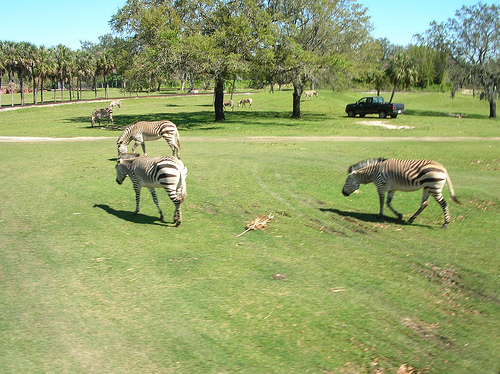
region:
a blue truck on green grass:
[336, 82, 413, 119]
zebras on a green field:
[86, 83, 471, 243]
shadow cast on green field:
[313, 191, 423, 238]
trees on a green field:
[6, 4, 484, 119]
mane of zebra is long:
[346, 153, 391, 178]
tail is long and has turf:
[446, 170, 463, 207]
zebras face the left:
[98, 111, 467, 241]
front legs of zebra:
[373, 193, 409, 225]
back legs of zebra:
[407, 193, 452, 230]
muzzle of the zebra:
[336, 184, 351, 201]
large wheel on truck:
[374, 111, 390, 122]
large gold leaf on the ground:
[223, 205, 284, 249]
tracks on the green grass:
[271, 175, 394, 276]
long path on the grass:
[225, 127, 443, 147]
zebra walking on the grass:
[96, 149, 209, 227]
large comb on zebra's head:
[336, 148, 406, 179]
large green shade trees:
[187, 26, 330, 123]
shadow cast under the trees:
[100, 85, 222, 130]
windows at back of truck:
[367, 92, 389, 104]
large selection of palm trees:
[20, 53, 127, 102]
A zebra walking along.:
[327, 149, 466, 233]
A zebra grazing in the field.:
[105, 118, 186, 159]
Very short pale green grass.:
[67, 260, 187, 330]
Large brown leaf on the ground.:
[220, 206, 282, 251]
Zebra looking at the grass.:
[107, 144, 196, 215]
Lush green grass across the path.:
[206, 118, 323, 133]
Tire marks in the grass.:
[345, 255, 482, 366]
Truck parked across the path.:
[340, 93, 412, 121]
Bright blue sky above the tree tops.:
[7, 24, 114, 57]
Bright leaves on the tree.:
[160, 27, 267, 124]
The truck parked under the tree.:
[348, 90, 403, 120]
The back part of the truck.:
[380, 98, 405, 116]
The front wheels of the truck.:
[342, 108, 365, 116]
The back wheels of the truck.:
[375, 108, 397, 119]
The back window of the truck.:
[371, 95, 384, 103]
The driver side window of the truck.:
[357, 96, 369, 103]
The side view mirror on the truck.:
[352, 100, 358, 106]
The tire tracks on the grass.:
[247, 147, 487, 358]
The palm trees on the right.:
[7, 36, 119, 95]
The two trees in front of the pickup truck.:
[101, 1, 324, 121]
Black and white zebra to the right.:
[341, 153, 463, 228]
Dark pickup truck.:
[346, 95, 406, 119]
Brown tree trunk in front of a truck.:
[292, 88, 302, 120]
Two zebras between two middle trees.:
[223, 97, 254, 112]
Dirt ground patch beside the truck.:
[360, 117, 415, 129]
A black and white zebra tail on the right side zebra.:
[446, 168, 461, 205]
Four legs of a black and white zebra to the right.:
[373, 185, 449, 230]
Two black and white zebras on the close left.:
[107, 121, 188, 225]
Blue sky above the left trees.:
[0, 0, 95, 46]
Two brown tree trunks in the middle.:
[209, 67, 304, 120]